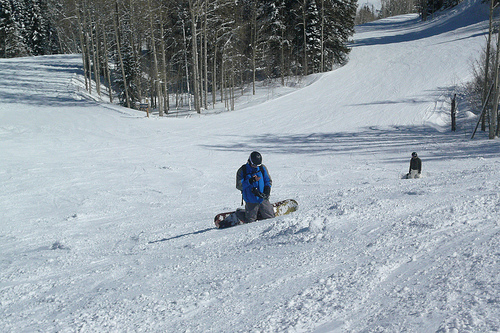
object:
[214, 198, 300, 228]
board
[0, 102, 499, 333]
ground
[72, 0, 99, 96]
tree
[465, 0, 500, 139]
tree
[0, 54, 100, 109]
shadows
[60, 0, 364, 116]
trees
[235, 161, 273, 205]
blue jacket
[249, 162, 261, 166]
goggles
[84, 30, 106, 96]
trunk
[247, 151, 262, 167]
helmet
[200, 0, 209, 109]
skinny tree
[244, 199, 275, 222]
pants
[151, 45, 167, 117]
tree trunk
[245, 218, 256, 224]
knee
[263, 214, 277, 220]
knee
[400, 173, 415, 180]
snowboard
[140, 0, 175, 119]
bare tree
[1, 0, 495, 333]
snow field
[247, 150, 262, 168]
head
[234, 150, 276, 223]
man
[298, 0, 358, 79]
tree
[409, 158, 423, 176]
coat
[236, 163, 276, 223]
body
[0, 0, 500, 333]
snow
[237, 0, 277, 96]
tree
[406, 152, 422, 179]
boy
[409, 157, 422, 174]
jacket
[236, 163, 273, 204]
coat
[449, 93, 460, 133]
tree stump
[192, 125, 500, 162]
shadows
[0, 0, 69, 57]
tree